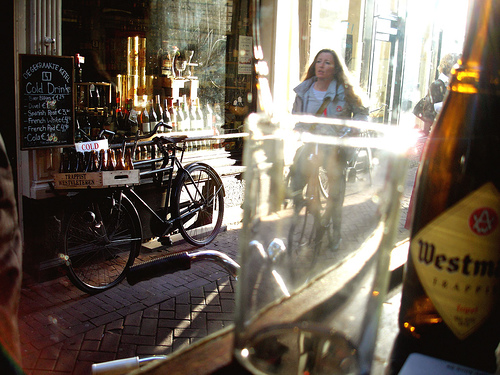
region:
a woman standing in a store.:
[266, 40, 370, 271]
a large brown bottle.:
[374, 3, 498, 344]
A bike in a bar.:
[58, 156, 248, 296]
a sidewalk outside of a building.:
[71, 182, 383, 374]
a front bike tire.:
[56, 182, 152, 297]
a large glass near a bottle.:
[217, 96, 438, 364]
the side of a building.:
[301, 0, 358, 90]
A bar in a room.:
[24, 29, 232, 145]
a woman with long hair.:
[286, 40, 374, 101]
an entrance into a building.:
[349, 0, 408, 137]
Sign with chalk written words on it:
[17, 53, 73, 146]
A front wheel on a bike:
[61, 186, 138, 289]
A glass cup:
[235, 114, 412, 374]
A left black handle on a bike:
[129, 250, 191, 285]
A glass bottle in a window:
[142, 105, 150, 133]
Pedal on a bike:
[159, 235, 171, 246]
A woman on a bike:
[289, 49, 366, 265]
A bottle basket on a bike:
[52, 151, 137, 188]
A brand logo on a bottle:
[410, 180, 498, 339]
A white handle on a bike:
[92, 355, 138, 374]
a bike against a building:
[85, 80, 317, 300]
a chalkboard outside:
[10, 31, 127, 186]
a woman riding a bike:
[244, 23, 429, 212]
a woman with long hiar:
[194, 16, 446, 286]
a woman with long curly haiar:
[240, 50, 400, 210]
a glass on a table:
[194, 66, 478, 373]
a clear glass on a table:
[204, 68, 494, 334]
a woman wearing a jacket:
[230, 26, 432, 226]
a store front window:
[46, 25, 285, 153]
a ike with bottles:
[72, 69, 309, 354]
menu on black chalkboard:
[15, 46, 80, 143]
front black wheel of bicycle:
[56, 190, 176, 279]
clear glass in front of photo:
[266, 120, 365, 332]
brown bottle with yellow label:
[396, 80, 498, 373]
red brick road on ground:
[109, 310, 178, 358]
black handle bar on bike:
[127, 246, 208, 301]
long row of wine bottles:
[136, 100, 202, 130]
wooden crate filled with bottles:
[48, 141, 148, 208]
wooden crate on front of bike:
[38, 140, 168, 227]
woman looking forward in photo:
[311, 42, 363, 101]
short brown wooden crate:
[53, 170, 140, 187]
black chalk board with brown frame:
[18, 53, 73, 145]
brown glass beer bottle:
[397, 0, 494, 354]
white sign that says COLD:
[73, 138, 107, 152]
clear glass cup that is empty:
[242, 112, 409, 370]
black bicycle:
[57, 121, 224, 288]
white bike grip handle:
[90, 353, 140, 373]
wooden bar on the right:
[133, 235, 406, 372]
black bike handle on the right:
[121, 249, 191, 284]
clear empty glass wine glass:
[175, 58, 185, 77]